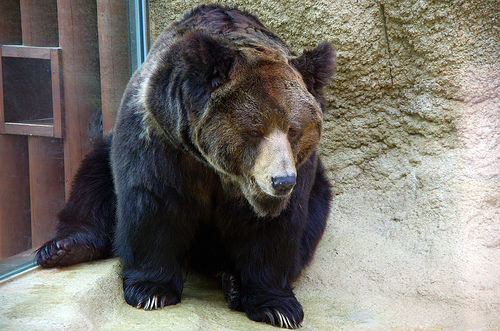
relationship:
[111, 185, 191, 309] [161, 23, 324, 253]
leg on bear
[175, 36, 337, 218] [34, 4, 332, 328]
head on bear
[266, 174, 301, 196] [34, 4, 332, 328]
nose of bear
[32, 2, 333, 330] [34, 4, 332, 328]
hair of bear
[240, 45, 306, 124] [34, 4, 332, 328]
hair of bear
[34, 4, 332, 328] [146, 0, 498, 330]
bear on rock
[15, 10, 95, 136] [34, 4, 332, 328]
glass next to bear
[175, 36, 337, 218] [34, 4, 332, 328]
head of bear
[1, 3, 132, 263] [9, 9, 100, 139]
wall of structure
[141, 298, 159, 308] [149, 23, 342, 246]
claws of bear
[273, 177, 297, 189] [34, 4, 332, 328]
nose of bear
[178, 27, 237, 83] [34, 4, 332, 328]
ear of bear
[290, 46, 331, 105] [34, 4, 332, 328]
ear of bear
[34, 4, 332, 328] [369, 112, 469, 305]
bear on stone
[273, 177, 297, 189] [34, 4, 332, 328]
nose on bear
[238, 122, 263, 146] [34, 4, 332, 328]
eye on bear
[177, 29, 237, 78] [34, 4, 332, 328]
ear of bear